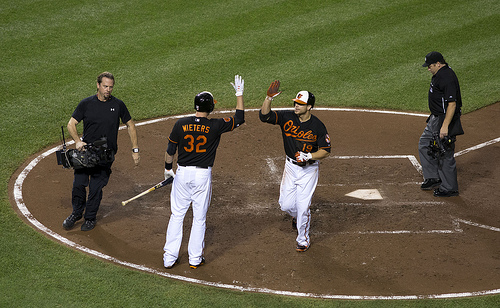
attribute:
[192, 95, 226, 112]
hat — black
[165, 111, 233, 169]
jersey — black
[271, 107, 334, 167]
jersey — black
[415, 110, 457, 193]
pants — gray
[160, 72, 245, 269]
player — baseball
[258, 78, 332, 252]
player — baseball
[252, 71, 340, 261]
player — black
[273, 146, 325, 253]
pants — white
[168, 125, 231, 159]
number — thirty two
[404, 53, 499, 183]
umpire — baseball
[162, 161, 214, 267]
pants — white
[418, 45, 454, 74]
hat — black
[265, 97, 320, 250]
clothes — white